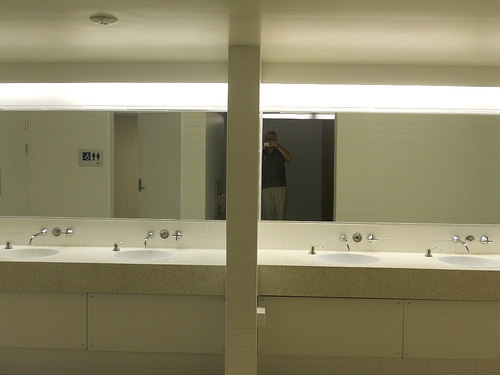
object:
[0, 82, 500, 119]
lighting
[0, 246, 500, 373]
counter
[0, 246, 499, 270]
basins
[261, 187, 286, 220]
pants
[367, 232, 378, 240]
tap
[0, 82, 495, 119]
lights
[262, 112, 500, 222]
reflection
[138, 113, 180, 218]
door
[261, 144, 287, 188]
black shirt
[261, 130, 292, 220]
man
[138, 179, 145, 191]
handle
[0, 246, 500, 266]
sinks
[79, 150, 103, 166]
bathroom sign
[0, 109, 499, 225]
mirror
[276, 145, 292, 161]
left arm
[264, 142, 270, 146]
phone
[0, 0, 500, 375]
comfort room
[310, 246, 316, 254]
dispenser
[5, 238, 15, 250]
soap dispenser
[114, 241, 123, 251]
soap dispenser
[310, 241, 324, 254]
soap dispenser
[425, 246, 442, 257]
soap dispenser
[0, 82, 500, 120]
light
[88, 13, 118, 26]
sprinkler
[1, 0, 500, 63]
ceiling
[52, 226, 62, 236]
knobs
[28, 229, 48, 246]
faucet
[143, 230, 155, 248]
faucet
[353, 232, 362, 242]
knobs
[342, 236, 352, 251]
facuet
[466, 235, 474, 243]
knobs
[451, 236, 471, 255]
faucet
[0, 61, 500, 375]
wall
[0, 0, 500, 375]
restroom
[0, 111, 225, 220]
reflection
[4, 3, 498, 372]
bathroom